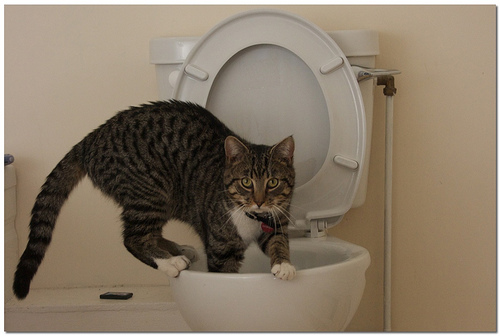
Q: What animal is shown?
A: Cat.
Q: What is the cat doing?
A: Playing in the toilet.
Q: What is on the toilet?
A: A cat.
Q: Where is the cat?
A: On the toilet.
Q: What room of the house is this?
A: Bathroom.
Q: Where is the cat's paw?
A: In the toilet.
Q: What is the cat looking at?
A: The camera.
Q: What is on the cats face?
A: Whiskers.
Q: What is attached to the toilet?
A: Pipe.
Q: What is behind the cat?
A: Toilet seat.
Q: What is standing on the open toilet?
A: The cat.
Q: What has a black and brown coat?
A: The cat.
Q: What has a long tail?
A: The cat.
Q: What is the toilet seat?
A: Up.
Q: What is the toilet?
A: White.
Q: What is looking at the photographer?
A: The cat.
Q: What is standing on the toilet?
A: The cat.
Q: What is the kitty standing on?
A: The white toilet.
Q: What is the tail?
A: Of the kitty.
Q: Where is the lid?
A: Toilet.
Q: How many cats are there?
A: 1.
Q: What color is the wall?
A: White.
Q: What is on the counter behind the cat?
A: A cell phone.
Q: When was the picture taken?
A: Day time.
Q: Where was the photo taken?
A: In a bathroom.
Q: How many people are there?
A: None.